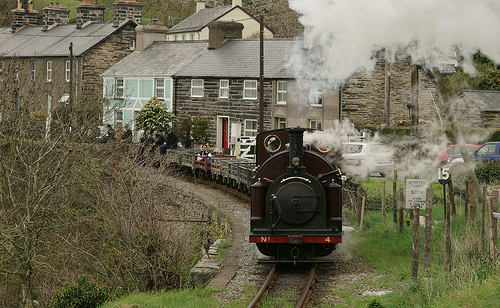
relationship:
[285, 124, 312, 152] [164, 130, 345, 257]
chimney of train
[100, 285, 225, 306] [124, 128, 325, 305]
vegetation by side of road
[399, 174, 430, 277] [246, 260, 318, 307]
sign next to rail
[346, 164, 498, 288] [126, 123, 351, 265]
fence next to train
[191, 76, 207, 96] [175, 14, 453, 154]
window on building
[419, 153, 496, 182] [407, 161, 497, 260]
cars next to fence